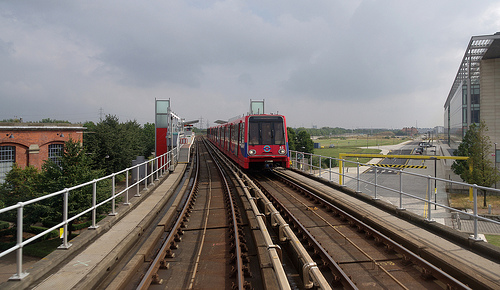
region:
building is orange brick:
[4, 118, 89, 197]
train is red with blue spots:
[194, 100, 308, 187]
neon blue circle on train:
[260, 137, 272, 157]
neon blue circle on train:
[257, 142, 275, 155]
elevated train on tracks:
[138, 79, 384, 261]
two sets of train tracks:
[182, 121, 367, 279]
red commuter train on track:
[201, 108, 302, 175]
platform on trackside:
[139, 91, 200, 170]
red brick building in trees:
[6, 113, 98, 183]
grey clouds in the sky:
[11, 5, 451, 113]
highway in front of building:
[365, 107, 466, 227]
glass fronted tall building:
[430, 65, 485, 202]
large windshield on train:
[240, 105, 292, 162]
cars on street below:
[406, 132, 448, 172]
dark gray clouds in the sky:
[70, 13, 214, 73]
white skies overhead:
[304, 96, 422, 123]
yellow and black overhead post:
[360, 148, 457, 188]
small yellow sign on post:
[43, 223, 88, 250]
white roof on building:
[10, 123, 95, 137]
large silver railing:
[28, 161, 195, 226]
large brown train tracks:
[157, 201, 401, 284]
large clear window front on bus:
[240, 111, 291, 145]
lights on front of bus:
[228, 148, 313, 170]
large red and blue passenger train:
[198, 95, 318, 203]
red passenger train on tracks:
[208, 111, 300, 189]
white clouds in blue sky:
[20, 12, 58, 50]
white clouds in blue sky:
[108, 55, 145, 86]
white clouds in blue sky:
[185, 6, 215, 41]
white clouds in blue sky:
[380, 79, 400, 99]